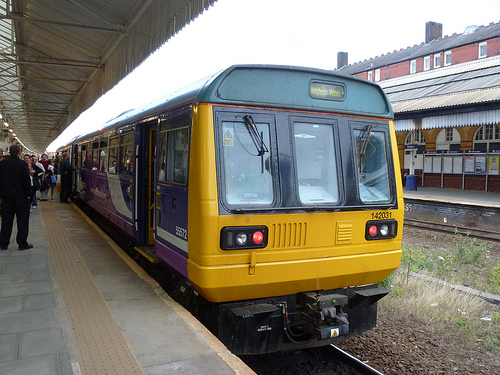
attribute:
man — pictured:
[0, 140, 37, 252]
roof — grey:
[343, 29, 487, 64]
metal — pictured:
[322, 337, 393, 374]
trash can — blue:
[403, 170, 418, 195]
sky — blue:
[220, 8, 331, 55]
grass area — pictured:
[409, 234, 496, 332]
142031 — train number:
[369, 209, 398, 219]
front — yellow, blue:
[196, 57, 411, 326]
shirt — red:
[40, 159, 50, 166]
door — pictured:
[137, 118, 159, 261]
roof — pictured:
[397, 55, 498, 112]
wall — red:
[342, 19, 499, 89]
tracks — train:
[391, 201, 499, 301]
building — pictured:
[395, 8, 498, 197]